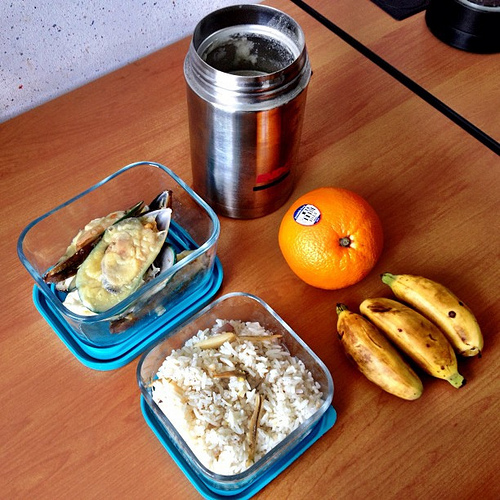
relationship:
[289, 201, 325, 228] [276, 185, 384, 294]
sticker on orange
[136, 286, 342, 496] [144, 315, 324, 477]
bowl of rice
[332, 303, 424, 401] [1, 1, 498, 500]
bananas on table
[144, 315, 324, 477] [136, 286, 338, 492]
rice in bowl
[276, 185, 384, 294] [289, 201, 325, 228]
orange has sticker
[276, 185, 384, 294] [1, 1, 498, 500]
orange on table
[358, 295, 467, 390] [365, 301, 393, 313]
plantain has mark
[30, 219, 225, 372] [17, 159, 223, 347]
cover under container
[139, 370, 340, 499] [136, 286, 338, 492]
cover under bowl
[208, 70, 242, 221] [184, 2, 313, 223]
reflection on metal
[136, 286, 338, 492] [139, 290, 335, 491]
bowl has rim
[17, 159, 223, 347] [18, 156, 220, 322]
container has rim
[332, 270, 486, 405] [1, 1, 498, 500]
bananas on table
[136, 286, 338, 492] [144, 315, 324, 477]
bowl has rice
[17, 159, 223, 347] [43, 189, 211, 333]
container has food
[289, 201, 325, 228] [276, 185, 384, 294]
price sticker on orange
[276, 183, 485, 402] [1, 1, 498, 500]
fruit on table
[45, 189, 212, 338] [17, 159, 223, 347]
oysters in container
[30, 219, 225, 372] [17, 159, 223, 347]
cover underneath container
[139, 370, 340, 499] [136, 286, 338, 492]
cover underneath bowl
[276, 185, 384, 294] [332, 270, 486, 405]
orange next to bananas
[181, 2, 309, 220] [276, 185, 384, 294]
container next to orange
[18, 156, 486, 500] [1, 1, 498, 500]
food on table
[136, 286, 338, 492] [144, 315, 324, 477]
bowl filled with rice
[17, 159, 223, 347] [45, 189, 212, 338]
container with oysters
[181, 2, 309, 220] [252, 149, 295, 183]
container has lettering